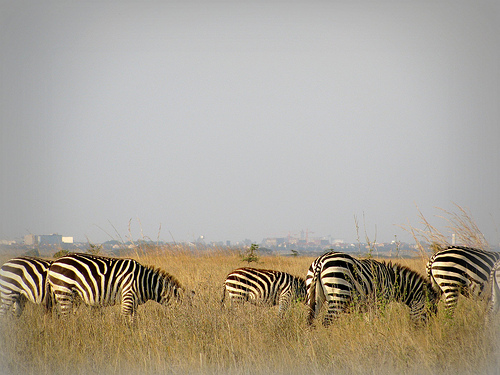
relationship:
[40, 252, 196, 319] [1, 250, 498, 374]
zebra grazing in field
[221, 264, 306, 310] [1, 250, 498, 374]
zebra grazing in field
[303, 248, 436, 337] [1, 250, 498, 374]
zebra grazing in field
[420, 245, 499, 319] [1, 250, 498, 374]
zebra grazing in field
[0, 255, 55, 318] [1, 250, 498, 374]
animal grazing in field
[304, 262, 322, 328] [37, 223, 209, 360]
tail on zebra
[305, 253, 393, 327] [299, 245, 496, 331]
body of zebras